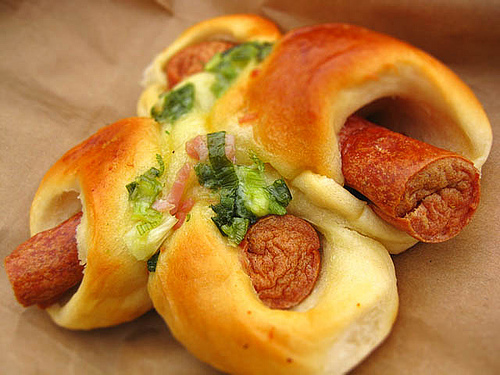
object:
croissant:
[135, 14, 282, 119]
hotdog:
[5, 209, 85, 310]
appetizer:
[3, 14, 495, 375]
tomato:
[186, 133, 236, 164]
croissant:
[147, 181, 401, 374]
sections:
[246, 21, 493, 255]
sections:
[151, 170, 398, 373]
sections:
[6, 116, 164, 332]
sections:
[138, 12, 290, 125]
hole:
[158, 28, 248, 95]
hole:
[238, 212, 328, 312]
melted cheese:
[161, 110, 209, 154]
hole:
[337, 94, 477, 209]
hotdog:
[165, 41, 235, 89]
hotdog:
[240, 214, 321, 310]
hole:
[30, 189, 88, 309]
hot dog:
[337, 114, 481, 243]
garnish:
[125, 131, 294, 273]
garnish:
[203, 38, 274, 99]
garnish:
[150, 82, 196, 124]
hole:
[125, 153, 166, 238]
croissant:
[28, 117, 170, 330]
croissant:
[205, 22, 494, 257]